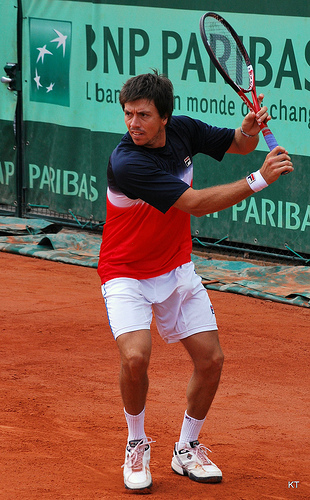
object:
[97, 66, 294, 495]
man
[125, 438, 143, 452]
black accents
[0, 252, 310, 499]
court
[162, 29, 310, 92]
word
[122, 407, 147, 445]
socks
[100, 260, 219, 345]
shorts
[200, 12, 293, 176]
racquet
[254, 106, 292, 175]
handle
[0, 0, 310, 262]
sign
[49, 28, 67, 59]
stars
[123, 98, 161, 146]
face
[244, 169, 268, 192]
band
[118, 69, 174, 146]
head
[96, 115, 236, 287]
shirt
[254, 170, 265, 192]
wrist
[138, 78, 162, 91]
hair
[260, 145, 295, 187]
hands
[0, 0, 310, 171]
wall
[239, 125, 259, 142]
watch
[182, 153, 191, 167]
logo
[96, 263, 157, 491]
legs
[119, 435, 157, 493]
right foot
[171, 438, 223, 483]
left foot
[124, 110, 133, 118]
eyes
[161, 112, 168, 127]
ear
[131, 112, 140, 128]
nose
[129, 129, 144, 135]
mouth